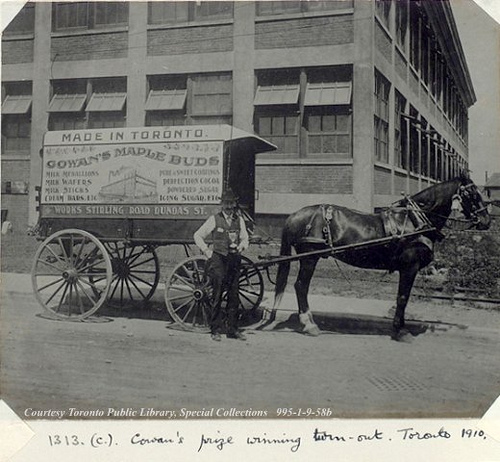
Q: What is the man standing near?
A: Horse and carriage.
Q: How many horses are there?
A: One.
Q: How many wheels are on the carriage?
A: Four.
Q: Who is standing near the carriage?
A: Man.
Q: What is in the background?
A: Building.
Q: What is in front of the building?
A: Grass.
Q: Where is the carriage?
A: Behind man.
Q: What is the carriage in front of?
A: Building.